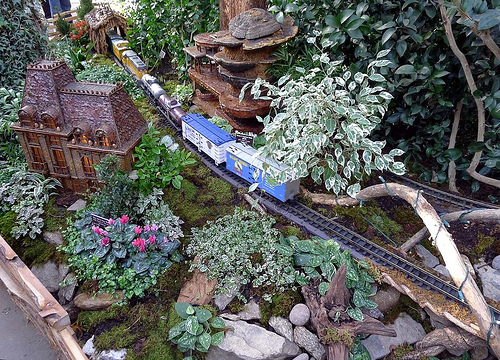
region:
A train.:
[97, 28, 305, 199]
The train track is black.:
[282, 197, 492, 329]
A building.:
[7, 52, 149, 183]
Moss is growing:
[173, 171, 234, 223]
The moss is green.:
[172, 170, 226, 222]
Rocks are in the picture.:
[216, 306, 326, 358]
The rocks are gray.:
[230, 302, 334, 358]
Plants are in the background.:
[295, 5, 487, 175]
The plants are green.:
[303, 3, 493, 168]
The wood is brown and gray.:
[315, 129, 495, 324]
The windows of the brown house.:
[17, 109, 120, 186]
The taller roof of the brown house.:
[19, 59, 66, 126]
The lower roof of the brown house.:
[62, 79, 134, 149]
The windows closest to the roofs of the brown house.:
[18, 105, 120, 147]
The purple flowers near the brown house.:
[88, 214, 165, 261]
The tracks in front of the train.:
[283, 198, 498, 306]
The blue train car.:
[227, 144, 302, 199]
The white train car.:
[176, 110, 225, 155]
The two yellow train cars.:
[110, 39, 146, 77]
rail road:
[307, 211, 414, 295]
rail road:
[330, 215, 448, 325]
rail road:
[300, 187, 374, 289]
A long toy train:
[93, 12, 315, 203]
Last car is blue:
[223, 144, 302, 205]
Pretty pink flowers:
[72, 203, 164, 274]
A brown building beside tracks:
[11, 53, 148, 211]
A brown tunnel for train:
[83, 6, 136, 63]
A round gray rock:
[292, 303, 319, 328]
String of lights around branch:
[323, 171, 499, 336]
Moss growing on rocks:
[19, 147, 283, 357]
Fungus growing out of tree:
[191, 9, 307, 112]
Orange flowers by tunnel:
[63, 16, 96, 55]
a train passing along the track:
[102, 27, 307, 202]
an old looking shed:
[86, 7, 134, 51]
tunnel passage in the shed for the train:
[104, 22, 127, 54]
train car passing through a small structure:
[102, 21, 121, 45]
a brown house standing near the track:
[13, 51, 150, 201]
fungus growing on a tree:
[181, 10, 311, 112]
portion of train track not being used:
[282, 199, 499, 316]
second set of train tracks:
[370, 160, 498, 219]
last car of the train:
[226, 136, 302, 202]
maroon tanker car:
[158, 90, 188, 134]